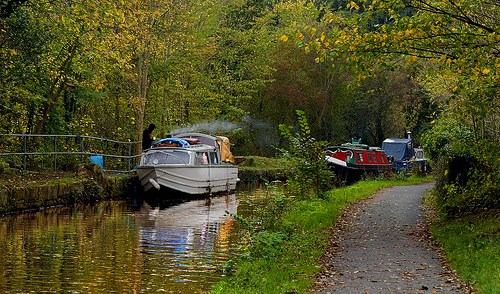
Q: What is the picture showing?
A: A river stream.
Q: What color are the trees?
A: Green.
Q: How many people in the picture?
A: One.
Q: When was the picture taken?
A: During the day.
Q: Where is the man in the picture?
A: Standing by the boat.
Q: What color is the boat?
A: White.